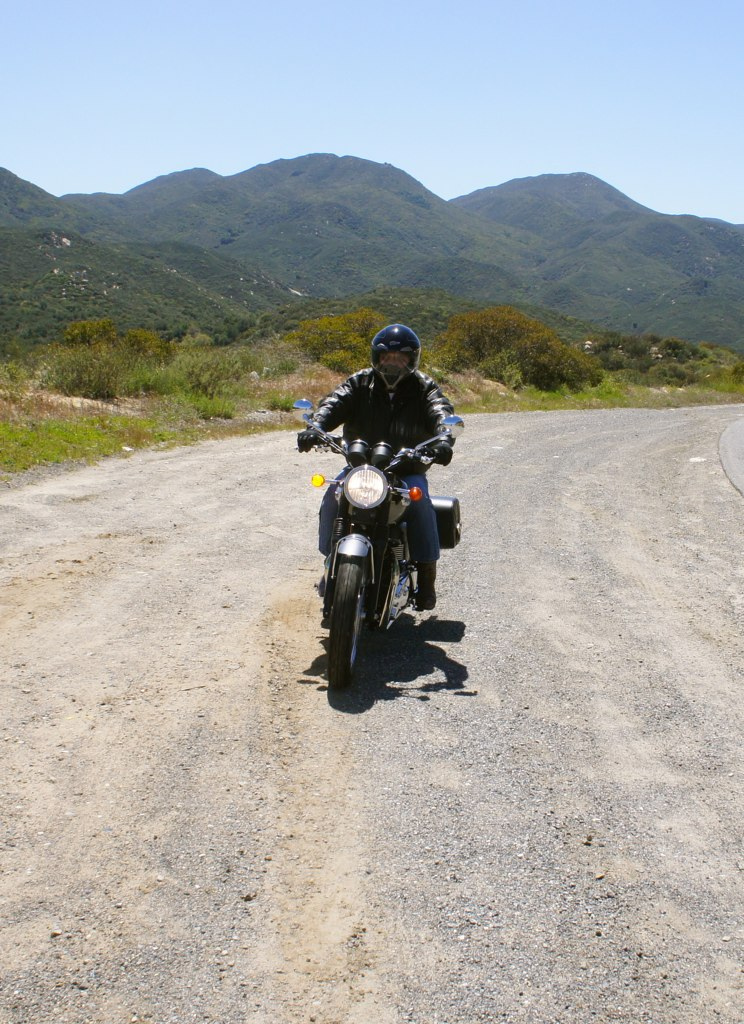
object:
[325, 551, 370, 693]
front wheel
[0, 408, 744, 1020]
ground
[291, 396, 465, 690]
motorcycle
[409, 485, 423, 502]
light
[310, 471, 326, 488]
light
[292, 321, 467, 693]
bike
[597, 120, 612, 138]
clouds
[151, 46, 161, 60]
clouds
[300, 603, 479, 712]
shadow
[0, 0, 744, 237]
sky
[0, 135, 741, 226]
haze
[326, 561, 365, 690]
tire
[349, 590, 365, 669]
wheel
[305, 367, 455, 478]
jacket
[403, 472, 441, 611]
legs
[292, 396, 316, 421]
mirror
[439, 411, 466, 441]
mirror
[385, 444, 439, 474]
handlebars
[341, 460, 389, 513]
headlight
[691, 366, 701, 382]
bushes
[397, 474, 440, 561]
jeans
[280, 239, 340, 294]
mountain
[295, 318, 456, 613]
cyclist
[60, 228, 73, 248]
rock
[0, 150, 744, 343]
mountain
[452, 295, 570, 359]
bush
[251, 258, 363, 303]
valley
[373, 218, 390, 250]
mountains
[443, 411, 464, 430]
surface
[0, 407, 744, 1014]
road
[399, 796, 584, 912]
gravel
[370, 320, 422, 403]
helmet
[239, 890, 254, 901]
rock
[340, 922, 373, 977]
rock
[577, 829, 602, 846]
rock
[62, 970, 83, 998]
rock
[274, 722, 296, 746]
rock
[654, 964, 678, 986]
rock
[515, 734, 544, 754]
rock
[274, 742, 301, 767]
rock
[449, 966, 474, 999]
rock